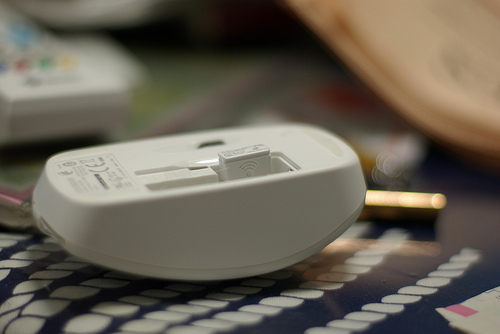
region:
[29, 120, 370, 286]
an upside down mouse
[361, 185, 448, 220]
a blurry shiny gold object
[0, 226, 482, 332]
blue cloth with rope design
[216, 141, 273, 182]
wireless insert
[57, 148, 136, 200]
label on bottom of mouse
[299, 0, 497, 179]
a blurry tan object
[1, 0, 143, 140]
a blurry white object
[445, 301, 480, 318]
a small pink rectangle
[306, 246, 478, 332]
a white rope design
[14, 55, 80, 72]
yellow, green and red buttons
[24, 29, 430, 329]
the charger is white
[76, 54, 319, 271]
the charger is white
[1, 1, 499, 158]
The background of the image is blurred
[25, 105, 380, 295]
A Computer mouse is in the foreground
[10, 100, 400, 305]
The computer mouse is white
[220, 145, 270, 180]
An icon of wifi bars on the mouse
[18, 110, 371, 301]
Computer mouse is upside down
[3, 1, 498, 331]
Photo was taken indoors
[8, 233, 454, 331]
Computer mouse is on a table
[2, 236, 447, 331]
The table is blue in color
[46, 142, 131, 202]
A sticker is on the computer mouse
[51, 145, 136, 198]
The sticker is white in color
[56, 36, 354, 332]
the table has cloth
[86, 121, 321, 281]
the table has cloth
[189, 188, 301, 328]
the table has cloth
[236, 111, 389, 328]
the table has cloth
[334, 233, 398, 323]
the table has cloth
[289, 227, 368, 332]
the table has cloth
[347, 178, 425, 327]
the table has cloth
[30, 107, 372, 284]
whit mouse on the desk.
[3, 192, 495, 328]
the desk is blue and white.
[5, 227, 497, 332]
the desk is polkadot.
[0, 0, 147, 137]
the phone is blurry.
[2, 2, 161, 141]
the phone is white.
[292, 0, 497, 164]
brown blurry object in the background.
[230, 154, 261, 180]
wifi symbol on the object.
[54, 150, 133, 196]
grey text on the object.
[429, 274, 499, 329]
white paper on the desk.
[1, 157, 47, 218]
pink object on the desk.